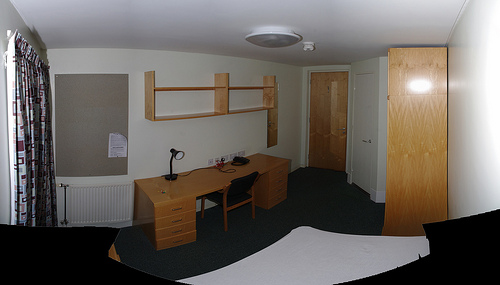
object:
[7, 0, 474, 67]
ceiling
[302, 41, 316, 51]
fire alarm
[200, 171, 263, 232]
chair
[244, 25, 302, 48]
ceiling light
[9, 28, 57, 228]
curtain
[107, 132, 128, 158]
paper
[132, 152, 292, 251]
desk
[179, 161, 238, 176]
cable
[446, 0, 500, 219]
wall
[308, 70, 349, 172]
closed door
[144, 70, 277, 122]
book shelf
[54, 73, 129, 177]
cork board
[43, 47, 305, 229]
wall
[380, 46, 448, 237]
wood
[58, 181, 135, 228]
radiator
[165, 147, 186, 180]
lamp